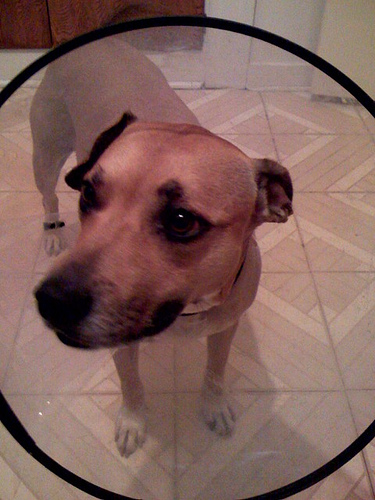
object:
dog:
[29, 37, 293, 457]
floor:
[2, 89, 375, 499]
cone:
[0, 17, 375, 499]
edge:
[189, 17, 373, 121]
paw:
[113, 403, 147, 459]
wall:
[0, 2, 375, 105]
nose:
[32, 278, 91, 325]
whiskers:
[94, 298, 141, 338]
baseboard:
[244, 0, 322, 92]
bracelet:
[43, 221, 65, 230]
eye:
[157, 207, 211, 243]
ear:
[254, 158, 294, 224]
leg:
[202, 321, 237, 394]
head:
[32, 109, 293, 351]